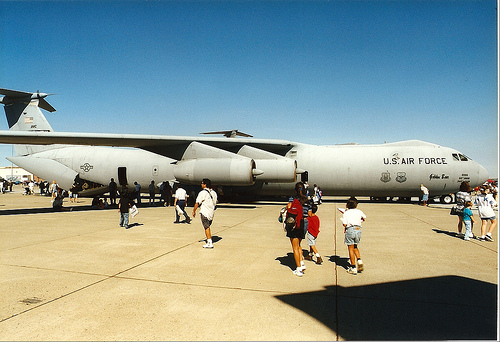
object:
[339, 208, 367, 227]
white shirt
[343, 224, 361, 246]
jean shorts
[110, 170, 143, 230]
people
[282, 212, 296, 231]
purse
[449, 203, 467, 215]
purse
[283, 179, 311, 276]
woman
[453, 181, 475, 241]
woman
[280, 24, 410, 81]
light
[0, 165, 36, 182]
building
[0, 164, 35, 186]
wall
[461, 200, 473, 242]
girl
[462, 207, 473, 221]
shirt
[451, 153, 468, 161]
window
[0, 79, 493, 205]
aircraft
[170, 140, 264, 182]
engine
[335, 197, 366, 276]
child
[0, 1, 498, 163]
blue sky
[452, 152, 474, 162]
cockpit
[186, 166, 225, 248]
man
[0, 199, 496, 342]
tarmac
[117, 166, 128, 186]
door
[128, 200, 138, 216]
bag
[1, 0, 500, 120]
clouds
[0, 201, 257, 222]
shadow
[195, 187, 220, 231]
attire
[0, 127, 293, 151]
wing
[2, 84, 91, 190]
tail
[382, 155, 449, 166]
air force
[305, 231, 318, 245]
shorts